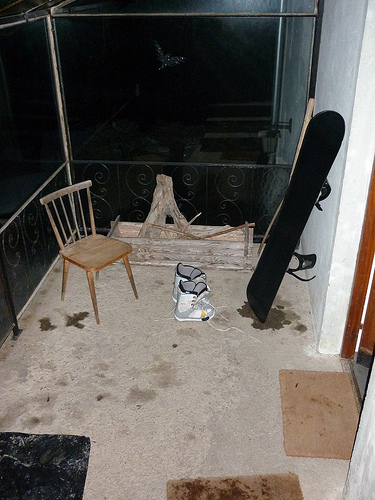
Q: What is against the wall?
A: Snowboard.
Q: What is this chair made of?
A: Wood.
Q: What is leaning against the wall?
A: Snowboard.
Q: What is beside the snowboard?
A: Boots.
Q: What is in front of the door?
A: Small carpet.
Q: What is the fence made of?
A: Metal.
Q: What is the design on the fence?
A: Swirls.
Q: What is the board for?
A: Snowboarding.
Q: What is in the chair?
A: Nothing.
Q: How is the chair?
A: Empty.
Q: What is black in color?
A: The snowboard.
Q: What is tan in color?
A: The rug.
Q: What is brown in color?
A: The chair.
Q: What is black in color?
A: The fence.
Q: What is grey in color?
A: The floor.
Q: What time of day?
A: It is night outside.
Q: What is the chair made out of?
A: Wood.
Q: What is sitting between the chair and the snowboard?
A: A pair of shoes.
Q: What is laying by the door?
A: A door mat.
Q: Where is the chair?
A: On the corner of the patio.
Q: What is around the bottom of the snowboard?
A: A puddle.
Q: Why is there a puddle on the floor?
A: The board is wet.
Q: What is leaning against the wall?
A: A snowboard.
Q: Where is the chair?
A: Near the black wall.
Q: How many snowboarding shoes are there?
A: Two.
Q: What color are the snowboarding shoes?
A: White.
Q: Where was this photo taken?
A: On a porch.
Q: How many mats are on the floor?
A: Three.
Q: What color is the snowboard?
A: Black.